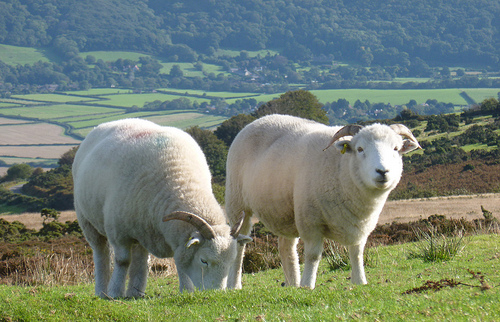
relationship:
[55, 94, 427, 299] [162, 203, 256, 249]
sheep with horns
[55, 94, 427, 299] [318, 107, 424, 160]
sheep with horns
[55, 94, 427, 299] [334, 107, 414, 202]
sheep has head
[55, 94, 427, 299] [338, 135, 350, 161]
sheep has tag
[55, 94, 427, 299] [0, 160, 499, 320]
sheep on hillside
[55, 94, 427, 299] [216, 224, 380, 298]
sheep have legs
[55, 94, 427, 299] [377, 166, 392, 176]
sheep has nose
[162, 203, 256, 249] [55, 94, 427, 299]
horns on sheep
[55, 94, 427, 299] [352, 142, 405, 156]
sheep have eyes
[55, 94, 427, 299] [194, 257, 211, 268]
sheep has eye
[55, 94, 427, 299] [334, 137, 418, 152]
sheep have ears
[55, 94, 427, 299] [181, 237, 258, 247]
sheep have ears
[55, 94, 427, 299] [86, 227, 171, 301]
sheep have legs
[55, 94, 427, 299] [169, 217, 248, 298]
sheep has head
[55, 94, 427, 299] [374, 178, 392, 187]
sheep has mouth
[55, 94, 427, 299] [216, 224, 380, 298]
sheep has legs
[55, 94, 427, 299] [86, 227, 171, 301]
sheep has legs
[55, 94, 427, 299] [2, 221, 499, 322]
sheep in grass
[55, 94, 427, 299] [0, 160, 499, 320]
sheep on mountain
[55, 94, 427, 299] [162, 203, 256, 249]
sheep has horns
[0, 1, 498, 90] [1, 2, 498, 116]
wilderness in distance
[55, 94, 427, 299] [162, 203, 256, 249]
sheep have horns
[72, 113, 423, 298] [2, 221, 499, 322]
sheep eats grass